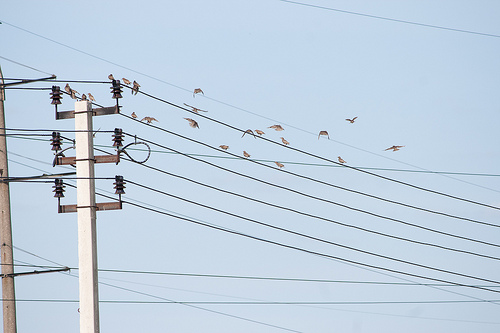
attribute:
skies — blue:
[235, 35, 498, 140]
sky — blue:
[220, 40, 497, 102]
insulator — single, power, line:
[108, 171, 128, 193]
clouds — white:
[125, 171, 366, 245]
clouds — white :
[313, 80, 476, 178]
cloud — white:
[285, 242, 472, 292]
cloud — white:
[100, 261, 317, 299]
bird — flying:
[383, 139, 414, 164]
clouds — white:
[126, 17, 422, 199]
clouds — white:
[89, 87, 446, 294]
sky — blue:
[124, 0, 499, 165]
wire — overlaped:
[116, 137, 153, 164]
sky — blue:
[203, 20, 445, 109]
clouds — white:
[144, 172, 319, 226]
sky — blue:
[0, 2, 499, 330]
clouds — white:
[149, 224, 355, 321]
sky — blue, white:
[404, 59, 479, 106]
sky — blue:
[212, 27, 433, 124]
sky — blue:
[4, 1, 499, 281]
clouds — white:
[367, 41, 425, 82]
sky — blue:
[147, 12, 276, 96]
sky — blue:
[378, 57, 445, 104]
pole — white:
[31, 86, 116, 273]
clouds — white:
[352, 107, 437, 164]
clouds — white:
[58, 16, 498, 327]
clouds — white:
[9, 7, 486, 327]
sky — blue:
[12, 11, 475, 331]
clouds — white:
[264, 55, 354, 95]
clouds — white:
[355, 59, 419, 99]